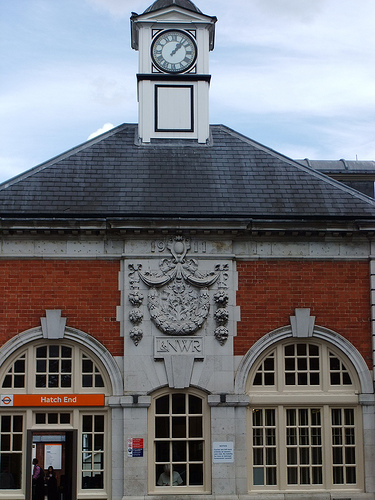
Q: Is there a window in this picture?
A: Yes, there is a window.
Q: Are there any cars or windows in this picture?
A: Yes, there is a window.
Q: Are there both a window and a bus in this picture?
A: No, there is a window but no buses.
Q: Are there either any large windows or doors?
A: Yes, there is a large window.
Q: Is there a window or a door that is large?
A: Yes, the window is large.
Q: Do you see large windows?
A: Yes, there is a large window.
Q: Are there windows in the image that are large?
A: Yes, there is a window that is large.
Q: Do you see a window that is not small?
A: Yes, there is a large window.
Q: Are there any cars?
A: No, there are no cars.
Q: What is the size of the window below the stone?
A: The window is large.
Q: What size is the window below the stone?
A: The window is large.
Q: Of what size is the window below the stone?
A: The window is large.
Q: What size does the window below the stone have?
A: The window has large size.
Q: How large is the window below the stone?
A: The window is large.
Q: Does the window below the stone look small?
A: No, the window is large.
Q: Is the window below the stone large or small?
A: The window is large.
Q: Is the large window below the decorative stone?
A: Yes, the window is below the stone.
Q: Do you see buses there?
A: No, there are no buses.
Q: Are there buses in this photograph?
A: No, there are no buses.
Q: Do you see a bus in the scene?
A: No, there are no buses.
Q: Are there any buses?
A: No, there are no buses.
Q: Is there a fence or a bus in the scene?
A: No, there are no buses or fences.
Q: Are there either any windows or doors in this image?
A: Yes, there is a window.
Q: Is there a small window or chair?
A: Yes, there is a small window.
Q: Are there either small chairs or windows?
A: Yes, there is a small window.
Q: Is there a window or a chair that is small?
A: Yes, the window is small.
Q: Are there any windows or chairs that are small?
A: Yes, the window is small.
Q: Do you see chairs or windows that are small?
A: Yes, the window is small.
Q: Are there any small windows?
A: Yes, there is a small window.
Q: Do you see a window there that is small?
A: Yes, there is a window that is small.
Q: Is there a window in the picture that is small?
A: Yes, there is a window that is small.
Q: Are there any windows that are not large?
A: Yes, there is a small window.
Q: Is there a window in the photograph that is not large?
A: Yes, there is a small window.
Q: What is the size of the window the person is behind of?
A: The window is small.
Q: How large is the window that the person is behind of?
A: The window is small.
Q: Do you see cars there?
A: No, there are no cars.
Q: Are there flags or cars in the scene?
A: No, there are no cars or flags.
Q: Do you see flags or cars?
A: No, there are no cars or flags.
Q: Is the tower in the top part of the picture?
A: Yes, the tower is in the top of the image.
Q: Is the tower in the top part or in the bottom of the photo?
A: The tower is in the top of the image.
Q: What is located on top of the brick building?
A: The tower is on top of the building.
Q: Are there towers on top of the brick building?
A: Yes, there is a tower on top of the building.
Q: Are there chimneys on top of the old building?
A: No, there is a tower on top of the building.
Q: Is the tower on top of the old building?
A: Yes, the tower is on top of the building.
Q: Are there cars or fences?
A: No, there are no cars or fences.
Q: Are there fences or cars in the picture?
A: No, there are no cars or fences.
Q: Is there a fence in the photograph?
A: No, there are no fences.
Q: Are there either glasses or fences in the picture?
A: No, there are no fences or glasses.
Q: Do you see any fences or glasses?
A: No, there are no fences or glasses.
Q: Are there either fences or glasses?
A: No, there are no fences or glasses.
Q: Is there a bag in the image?
A: No, there are no bags.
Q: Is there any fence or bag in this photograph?
A: No, there are no bags or fences.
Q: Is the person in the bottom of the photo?
A: Yes, the person is in the bottom of the image.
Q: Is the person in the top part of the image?
A: No, the person is in the bottom of the image.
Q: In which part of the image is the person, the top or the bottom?
A: The person is in the bottom of the image.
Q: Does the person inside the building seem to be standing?
A: Yes, the person is standing.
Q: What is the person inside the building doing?
A: The person is standing.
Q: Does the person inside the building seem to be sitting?
A: No, the person is standing.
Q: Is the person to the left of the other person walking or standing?
A: The person is standing.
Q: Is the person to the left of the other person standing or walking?
A: The person is standing.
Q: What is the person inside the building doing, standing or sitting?
A: The person is standing.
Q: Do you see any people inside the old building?
A: Yes, there is a person inside the building.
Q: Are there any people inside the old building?
A: Yes, there is a person inside the building.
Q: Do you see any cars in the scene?
A: No, there are no cars.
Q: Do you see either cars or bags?
A: No, there are no cars or bags.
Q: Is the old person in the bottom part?
A: Yes, the person is in the bottom of the image.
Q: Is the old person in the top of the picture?
A: No, the person is in the bottom of the image.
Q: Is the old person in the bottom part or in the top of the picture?
A: The person is in the bottom of the image.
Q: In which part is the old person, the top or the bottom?
A: The person is in the bottom of the image.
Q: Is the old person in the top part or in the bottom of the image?
A: The person is in the bottom of the image.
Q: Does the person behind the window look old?
A: Yes, the person is old.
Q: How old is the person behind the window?
A: The person is old.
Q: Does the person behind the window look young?
A: No, the person is old.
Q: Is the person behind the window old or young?
A: The person is old.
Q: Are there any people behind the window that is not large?
A: Yes, there is a person behind the window.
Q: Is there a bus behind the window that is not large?
A: No, there is a person behind the window.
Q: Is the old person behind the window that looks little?
A: Yes, the person is behind the window.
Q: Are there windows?
A: Yes, there are windows.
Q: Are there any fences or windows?
A: Yes, there are windows.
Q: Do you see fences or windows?
A: Yes, there are windows.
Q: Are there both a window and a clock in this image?
A: Yes, there are both a window and a clock.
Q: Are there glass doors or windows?
A: Yes, there are glass windows.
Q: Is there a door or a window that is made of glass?
A: Yes, the windows are made of glass.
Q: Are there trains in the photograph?
A: No, there are no trains.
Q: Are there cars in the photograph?
A: No, there are no cars.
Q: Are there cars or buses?
A: No, there are no cars or buses.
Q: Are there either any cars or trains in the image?
A: No, there are no cars or trains.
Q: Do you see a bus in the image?
A: No, there are no buses.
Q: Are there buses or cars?
A: No, there are no buses or cars.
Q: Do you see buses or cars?
A: No, there are no buses or cars.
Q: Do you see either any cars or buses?
A: No, there are no buses or cars.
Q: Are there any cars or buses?
A: No, there are no buses or cars.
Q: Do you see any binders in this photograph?
A: No, there are no binders.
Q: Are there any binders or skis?
A: No, there are no binders or skis.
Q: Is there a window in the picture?
A: Yes, there are windows.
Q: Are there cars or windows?
A: Yes, there are windows.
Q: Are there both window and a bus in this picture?
A: No, there are windows but no buses.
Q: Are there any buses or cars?
A: No, there are no cars or buses.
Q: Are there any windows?
A: Yes, there is a window.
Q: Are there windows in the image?
A: Yes, there is a window.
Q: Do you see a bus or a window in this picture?
A: Yes, there is a window.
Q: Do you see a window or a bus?
A: Yes, there is a window.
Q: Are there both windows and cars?
A: No, there is a window but no cars.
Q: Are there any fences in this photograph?
A: No, there are no fences.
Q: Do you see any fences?
A: No, there are no fences.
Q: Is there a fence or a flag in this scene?
A: No, there are no fences or flags.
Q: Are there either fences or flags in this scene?
A: No, there are no fences or flags.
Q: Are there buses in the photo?
A: No, there are no buses.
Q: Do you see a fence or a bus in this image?
A: No, there are no buses or fences.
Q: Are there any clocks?
A: Yes, there is a clock.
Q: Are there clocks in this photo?
A: Yes, there is a clock.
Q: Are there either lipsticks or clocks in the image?
A: Yes, there is a clock.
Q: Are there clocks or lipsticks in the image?
A: Yes, there is a clock.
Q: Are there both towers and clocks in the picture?
A: Yes, there are both a clock and a tower.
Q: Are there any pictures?
A: No, there are no pictures.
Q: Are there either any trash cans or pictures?
A: No, there are no pictures or trash cans.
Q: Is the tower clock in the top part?
A: Yes, the clock is in the top of the image.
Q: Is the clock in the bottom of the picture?
A: No, the clock is in the top of the image.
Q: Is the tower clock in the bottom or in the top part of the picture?
A: The clock is in the top of the image.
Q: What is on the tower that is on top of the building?
A: The clock is on the tower.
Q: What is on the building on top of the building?
A: The clock is on the tower.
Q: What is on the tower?
A: The clock is on the tower.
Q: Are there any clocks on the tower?
A: Yes, there is a clock on the tower.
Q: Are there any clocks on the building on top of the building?
A: Yes, there is a clock on the tower.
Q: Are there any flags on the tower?
A: No, there is a clock on the tower.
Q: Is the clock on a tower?
A: Yes, the clock is on a tower.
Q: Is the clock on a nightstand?
A: No, the clock is on a tower.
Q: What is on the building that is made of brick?
A: The clock is on the building.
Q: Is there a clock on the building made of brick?
A: Yes, there is a clock on the building.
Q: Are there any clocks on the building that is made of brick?
A: Yes, there is a clock on the building.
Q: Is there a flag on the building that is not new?
A: No, there is a clock on the building.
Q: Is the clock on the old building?
A: Yes, the clock is on the building.